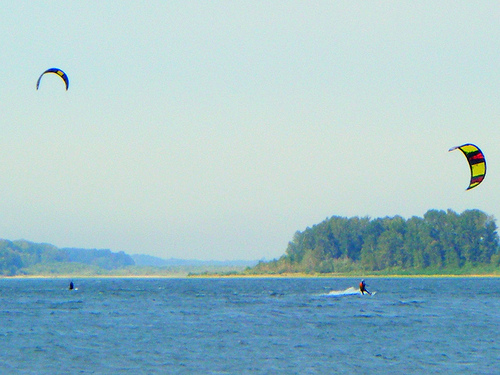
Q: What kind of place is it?
A: It is a lake.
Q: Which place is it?
A: It is a lake.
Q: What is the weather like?
A: It is cloudy.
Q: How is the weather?
A: It is cloudy.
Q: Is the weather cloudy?
A: Yes, it is cloudy.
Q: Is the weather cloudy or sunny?
A: It is cloudy.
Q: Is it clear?
A: No, it is cloudy.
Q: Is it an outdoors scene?
A: Yes, it is outdoors.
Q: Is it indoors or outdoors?
A: It is outdoors.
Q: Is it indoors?
A: No, it is outdoors.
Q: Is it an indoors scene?
A: No, it is outdoors.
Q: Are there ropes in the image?
A: No, there are no ropes.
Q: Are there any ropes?
A: No, there are no ropes.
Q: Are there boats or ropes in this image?
A: No, there are no ropes or boats.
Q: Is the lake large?
A: Yes, the lake is large.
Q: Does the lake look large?
A: Yes, the lake is large.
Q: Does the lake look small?
A: No, the lake is large.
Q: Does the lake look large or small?
A: The lake is large.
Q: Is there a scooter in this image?
A: No, there are no scooters.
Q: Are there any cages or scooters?
A: No, there are no scooters or cages.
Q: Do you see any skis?
A: No, there are no skis.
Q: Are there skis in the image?
A: No, there are no skis.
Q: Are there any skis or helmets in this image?
A: No, there are no skis or helmets.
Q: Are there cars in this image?
A: No, there are no cars.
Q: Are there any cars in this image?
A: No, there are no cars.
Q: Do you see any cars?
A: No, there are no cars.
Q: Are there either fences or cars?
A: No, there are no cars or fences.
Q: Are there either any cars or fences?
A: No, there are no cars or fences.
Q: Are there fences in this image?
A: No, there are no fences.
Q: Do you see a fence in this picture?
A: No, there are no fences.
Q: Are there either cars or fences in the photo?
A: No, there are no fences or cars.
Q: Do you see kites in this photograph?
A: Yes, there is a kite.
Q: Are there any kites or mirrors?
A: Yes, there is a kite.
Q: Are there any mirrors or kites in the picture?
A: Yes, there is a kite.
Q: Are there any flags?
A: No, there are no flags.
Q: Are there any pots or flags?
A: No, there are no flags or pots.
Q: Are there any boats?
A: No, there are no boats.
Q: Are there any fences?
A: No, there are no fences.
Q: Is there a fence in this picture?
A: No, there are no fences.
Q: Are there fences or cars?
A: No, there are no fences or cars.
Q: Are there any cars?
A: No, there are no cars.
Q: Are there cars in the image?
A: No, there are no cars.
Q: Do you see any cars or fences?
A: No, there are no cars or fences.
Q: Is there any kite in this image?
A: Yes, there is a kite.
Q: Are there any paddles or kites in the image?
A: Yes, there is a kite.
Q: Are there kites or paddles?
A: Yes, there is a kite.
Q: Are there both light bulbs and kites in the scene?
A: No, there is a kite but no light bulbs.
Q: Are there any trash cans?
A: No, there are no trash cans.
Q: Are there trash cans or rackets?
A: No, there are no trash cans or rackets.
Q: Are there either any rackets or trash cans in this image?
A: No, there are no trash cans or rackets.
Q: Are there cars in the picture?
A: No, there are no cars.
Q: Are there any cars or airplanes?
A: No, there are no cars or airplanes.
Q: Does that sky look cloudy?
A: Yes, the sky is cloudy.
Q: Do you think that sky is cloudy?
A: Yes, the sky is cloudy.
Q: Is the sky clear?
A: No, the sky is cloudy.